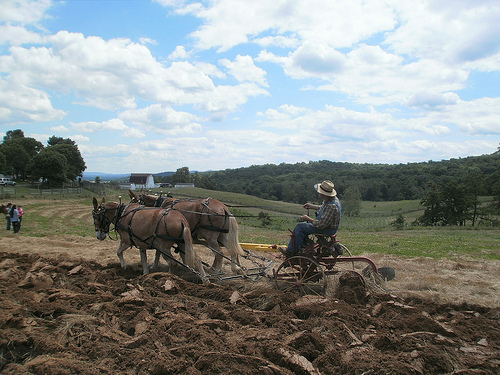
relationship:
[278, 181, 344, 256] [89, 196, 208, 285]
farmer pulled by horse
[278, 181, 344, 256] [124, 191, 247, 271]
farmer pulled by horse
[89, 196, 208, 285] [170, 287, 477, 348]
horse making furrow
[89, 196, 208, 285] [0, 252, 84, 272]
horse making furrow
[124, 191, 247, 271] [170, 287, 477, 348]
horse making furrow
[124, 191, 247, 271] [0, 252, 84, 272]
horse making furrow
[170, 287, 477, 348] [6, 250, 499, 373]
furrow in field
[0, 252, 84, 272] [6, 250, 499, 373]
furrow in field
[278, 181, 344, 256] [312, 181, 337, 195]
farmer wearing hat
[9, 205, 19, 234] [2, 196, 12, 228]
people of person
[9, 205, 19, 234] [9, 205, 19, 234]
people of people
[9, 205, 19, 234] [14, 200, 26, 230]
people of person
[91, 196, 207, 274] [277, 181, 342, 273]
horse pulling man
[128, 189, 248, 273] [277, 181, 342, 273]
horse pulling man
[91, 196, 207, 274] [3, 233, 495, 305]
horse on road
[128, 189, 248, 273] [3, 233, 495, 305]
horse on road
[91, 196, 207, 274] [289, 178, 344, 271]
horse pulling man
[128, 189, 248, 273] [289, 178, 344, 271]
horse pulling man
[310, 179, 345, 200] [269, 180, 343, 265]
hat on man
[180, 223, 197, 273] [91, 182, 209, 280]
tail on horse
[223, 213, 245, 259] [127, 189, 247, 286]
tail on horse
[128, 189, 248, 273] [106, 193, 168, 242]
horse wearing bridles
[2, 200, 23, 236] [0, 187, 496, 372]
people standing in field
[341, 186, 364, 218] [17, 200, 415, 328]
tree on outskirt of field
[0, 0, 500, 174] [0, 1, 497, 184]
sky with clouds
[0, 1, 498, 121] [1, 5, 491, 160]
cloud in sky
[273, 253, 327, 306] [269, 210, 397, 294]
wheel of tilling equipment